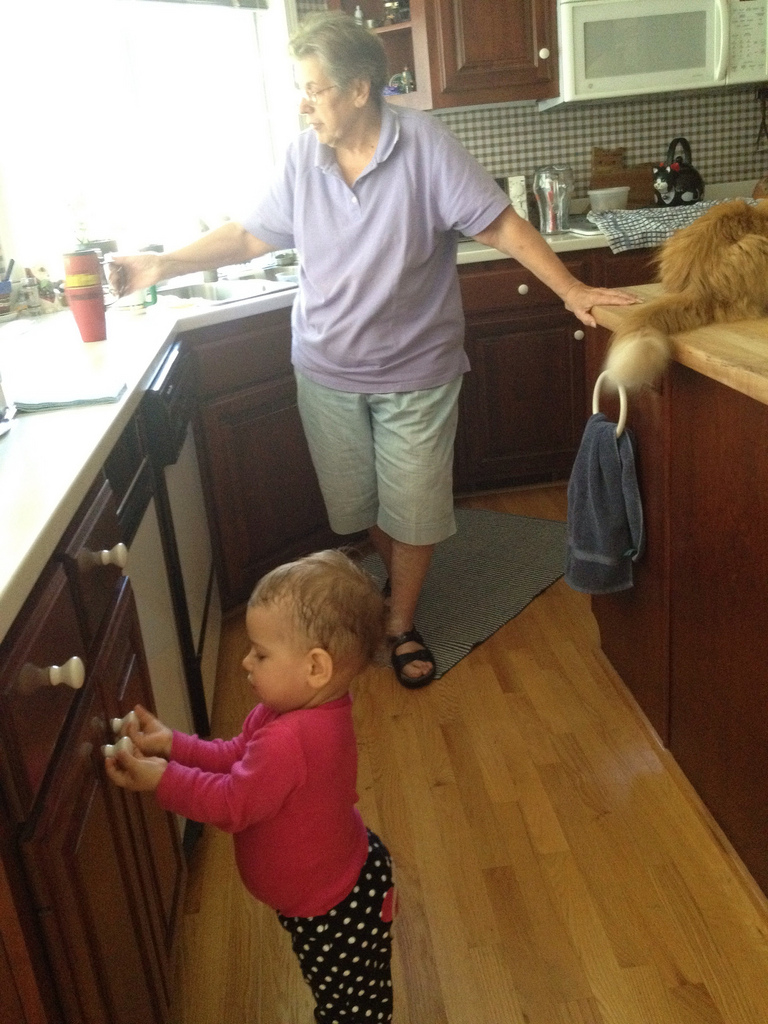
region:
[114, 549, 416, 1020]
Toddler trying to open cupboard doors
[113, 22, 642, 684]
older woman wearing a purple shirt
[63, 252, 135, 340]
white and yellow coffee mug for keeping it hot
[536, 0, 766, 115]
white microwave for cooking food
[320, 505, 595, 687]
gray rub to prevent slipping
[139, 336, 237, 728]
black and white dishwasher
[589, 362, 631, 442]
white ring for holding towels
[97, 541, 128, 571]
white handle for opening drawer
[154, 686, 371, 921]
A long sleeve pink shirt.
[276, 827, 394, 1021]
Black pants with white polka dots.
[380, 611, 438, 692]
A woman's left foot with sandal.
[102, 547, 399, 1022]
A brown haired girl with black polka dot pants.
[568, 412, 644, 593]
A grey hand towel.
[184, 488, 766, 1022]
A brown wood floor.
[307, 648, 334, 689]
A childs left ear.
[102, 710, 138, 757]
Two white knobs a girl is holding.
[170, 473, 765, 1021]
brown wood floor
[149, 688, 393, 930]
pink long-sleeved shirt on toddler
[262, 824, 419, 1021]
black toddler's pants with white polka dots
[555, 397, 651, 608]
blue towel hanging in a ring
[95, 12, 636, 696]
Woman wearing lavendar short-sleeved shirt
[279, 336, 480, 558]
pair of khaki colored shorts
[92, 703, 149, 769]
two door knobs being touched by toddler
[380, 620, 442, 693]
black sandal worn by the woman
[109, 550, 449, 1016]
A young child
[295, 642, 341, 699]
The left ear of the baby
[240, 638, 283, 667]
An eye of the baby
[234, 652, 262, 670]
The nose of the baby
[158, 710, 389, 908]
The pink shirt of the baby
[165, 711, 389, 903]
A long sleeved pink shirt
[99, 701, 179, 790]
The hands of the baby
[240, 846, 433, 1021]
The black dotted pants of the baby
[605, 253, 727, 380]
a tail on the cat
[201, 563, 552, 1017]
a child standin gin the kitchen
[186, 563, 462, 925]
a child wearing a shirt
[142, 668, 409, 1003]
a child wearing apnts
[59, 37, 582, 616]
A person holding a coffee mug.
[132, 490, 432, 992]
A small child holding onto the cabinet knobs with both hands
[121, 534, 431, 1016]
A small child with a long sleeve red shirt on.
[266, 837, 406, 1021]
Black pants with white polka dots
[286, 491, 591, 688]
A rectangular rug on the ground.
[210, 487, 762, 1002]
Light brown hardwood floors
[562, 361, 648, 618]
A blue dish towel hanging up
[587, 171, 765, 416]
An orange cat on the countertop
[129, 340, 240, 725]
A black and white dishwasher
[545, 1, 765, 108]
A white microwave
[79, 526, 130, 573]
a knob on the drawer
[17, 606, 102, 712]
a knob on the drawer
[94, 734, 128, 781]
a knob on the drawer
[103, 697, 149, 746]
a knob on the drawer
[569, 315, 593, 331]
a knob on the drawer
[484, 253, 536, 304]
a knob on the drawer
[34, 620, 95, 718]
a brown wood drawer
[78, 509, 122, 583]
a brown wood drawer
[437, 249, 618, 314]
a brown wood drawer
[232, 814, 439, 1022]
black polka dotted bottoms